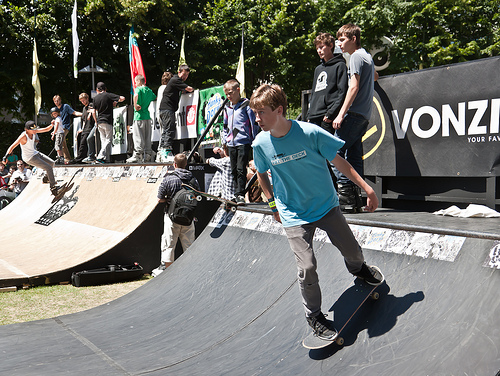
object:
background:
[19, 11, 437, 63]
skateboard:
[302, 265, 385, 350]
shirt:
[251, 119, 345, 227]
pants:
[283, 205, 364, 318]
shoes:
[305, 309, 339, 341]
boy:
[247, 84, 384, 342]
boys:
[332, 24, 375, 205]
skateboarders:
[2, 120, 65, 196]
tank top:
[20, 131, 40, 163]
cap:
[25, 121, 40, 131]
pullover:
[307, 53, 348, 120]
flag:
[70, 0, 79, 79]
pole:
[73, 79, 78, 97]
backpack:
[165, 183, 202, 226]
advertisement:
[390, 98, 499, 143]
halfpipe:
[70, 168, 151, 239]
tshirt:
[133, 86, 156, 120]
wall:
[387, 64, 463, 172]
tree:
[252, 16, 306, 81]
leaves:
[272, 45, 284, 55]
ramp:
[150, 263, 249, 347]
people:
[157, 64, 193, 151]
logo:
[391, 102, 467, 140]